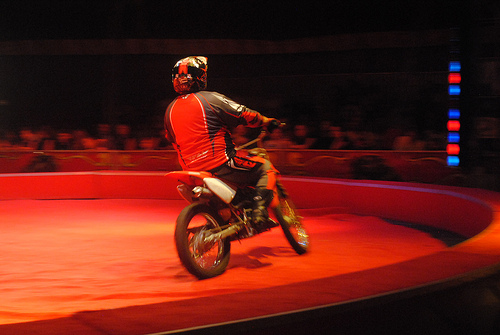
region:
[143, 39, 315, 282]
a man riding a motorcyle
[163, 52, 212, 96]
a red and black helmet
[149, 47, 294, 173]
a man wearing a motorcycle helmet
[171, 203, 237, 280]
the rear wheel of a motorcycle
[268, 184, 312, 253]
the front wheel of a motorcycle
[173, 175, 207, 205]
the muffler of a motorcycle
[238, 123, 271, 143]
the handle bar of a motorcycle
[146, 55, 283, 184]
a man wearing a red and black jacket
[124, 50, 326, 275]
a man racing a motocross bike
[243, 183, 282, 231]
a black motocross boot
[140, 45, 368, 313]
man riding a motorbike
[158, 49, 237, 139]
man is wearing a helmet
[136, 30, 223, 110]
man is wearing a helmet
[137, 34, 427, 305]
Man riding a motorcycle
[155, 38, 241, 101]
Man wearing a helmet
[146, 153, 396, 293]
Motorcycle has two wheels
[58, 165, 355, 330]
Track surrounding the man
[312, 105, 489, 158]
People in the audience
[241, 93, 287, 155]
Man holding the handlebar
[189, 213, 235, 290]
Spokes on the motorcycle wheel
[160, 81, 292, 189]
Man wearing a jacket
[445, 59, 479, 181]
Lights beside the track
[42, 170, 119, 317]
Light shining on the track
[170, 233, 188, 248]
the back tire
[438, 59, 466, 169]
lights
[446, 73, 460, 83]
a red light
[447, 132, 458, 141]
a blue light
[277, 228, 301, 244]
the front tire of the motorcycle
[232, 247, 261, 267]
a shadow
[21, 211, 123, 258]
the pit is red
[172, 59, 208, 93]
biker is wearing a helmet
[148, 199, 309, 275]
a motorcycle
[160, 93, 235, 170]
a red and black shirt